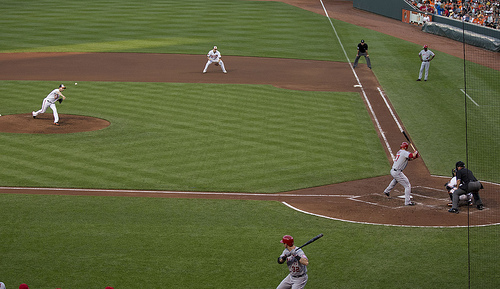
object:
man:
[201, 46, 227, 75]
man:
[383, 141, 420, 207]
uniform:
[384, 141, 414, 206]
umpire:
[445, 160, 486, 214]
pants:
[448, 182, 482, 208]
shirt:
[456, 168, 479, 184]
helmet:
[399, 142, 409, 149]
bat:
[401, 128, 419, 153]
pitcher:
[30, 83, 68, 126]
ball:
[72, 82, 79, 86]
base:
[351, 84, 365, 90]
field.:
[3, 3, 499, 288]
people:
[414, 45, 435, 82]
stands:
[351, 1, 497, 53]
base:
[398, 193, 414, 201]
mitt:
[217, 64, 221, 67]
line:
[320, 2, 396, 162]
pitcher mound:
[0, 111, 112, 135]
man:
[272, 234, 309, 289]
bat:
[292, 232, 322, 252]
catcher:
[442, 168, 484, 207]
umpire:
[351, 40, 373, 71]